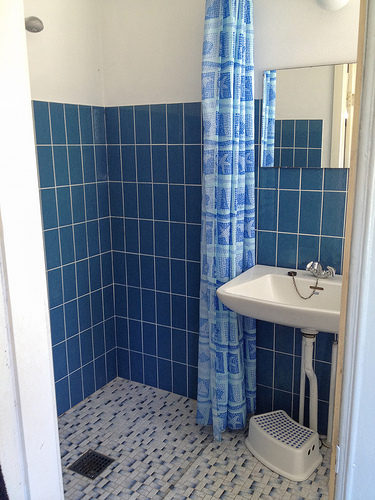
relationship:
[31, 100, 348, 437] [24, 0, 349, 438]
tiles on walls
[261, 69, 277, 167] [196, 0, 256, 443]
reflection of shower curtain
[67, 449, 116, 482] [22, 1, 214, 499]
drain in shower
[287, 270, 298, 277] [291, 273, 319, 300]
sink plug attached to chain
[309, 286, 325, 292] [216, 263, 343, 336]
overflow opening in sink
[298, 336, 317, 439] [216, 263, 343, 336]
pipes under sink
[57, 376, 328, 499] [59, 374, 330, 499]
tiles on floor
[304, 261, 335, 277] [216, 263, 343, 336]
water fixtures on sink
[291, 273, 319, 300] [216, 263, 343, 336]
chain on sink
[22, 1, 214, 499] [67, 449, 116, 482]
shower has a drain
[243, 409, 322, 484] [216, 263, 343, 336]
stool under sink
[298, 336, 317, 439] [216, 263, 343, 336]
pipes are under sink